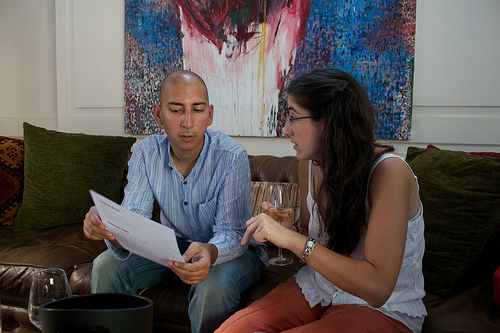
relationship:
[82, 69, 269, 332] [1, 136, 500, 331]
man sitting on couch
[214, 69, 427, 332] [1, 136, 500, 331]
woman sitting on couch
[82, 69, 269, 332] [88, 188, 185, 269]
man holding paper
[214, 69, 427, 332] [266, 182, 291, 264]
woman holding wine glass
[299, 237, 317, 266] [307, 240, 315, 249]
watch has face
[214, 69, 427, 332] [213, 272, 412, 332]
woman wearing pants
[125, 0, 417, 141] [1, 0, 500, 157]
art on wall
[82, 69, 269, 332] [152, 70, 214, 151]
man has head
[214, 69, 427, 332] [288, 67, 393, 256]
woman has hair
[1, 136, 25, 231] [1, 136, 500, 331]
pillow on couch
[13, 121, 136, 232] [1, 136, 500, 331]
throw pillow on couch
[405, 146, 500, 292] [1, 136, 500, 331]
throw pillow on couch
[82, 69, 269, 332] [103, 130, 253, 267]
man wearing shirt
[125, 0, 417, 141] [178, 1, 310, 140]
art has middle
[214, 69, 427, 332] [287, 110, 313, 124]
woman wearing glasses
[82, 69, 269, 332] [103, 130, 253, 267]
man wears shirt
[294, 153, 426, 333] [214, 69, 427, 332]
tank top on woman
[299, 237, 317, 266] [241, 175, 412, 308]
watch on arm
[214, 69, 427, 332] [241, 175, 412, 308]
woman has arm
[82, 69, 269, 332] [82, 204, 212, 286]
man has hands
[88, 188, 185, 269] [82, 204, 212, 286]
paper in hands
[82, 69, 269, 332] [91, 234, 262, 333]
man wearing jeans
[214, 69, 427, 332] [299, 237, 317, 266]
woman wearing watch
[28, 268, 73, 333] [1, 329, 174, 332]
wine goblet on table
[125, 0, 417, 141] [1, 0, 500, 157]
art hanging on wall